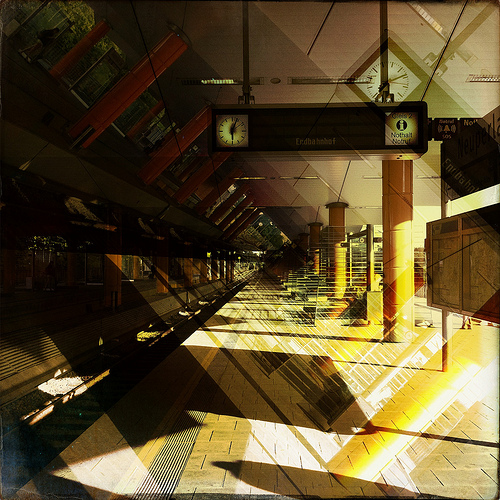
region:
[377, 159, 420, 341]
a cylindrical orange column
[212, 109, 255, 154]
a clock at a train station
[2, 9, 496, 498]
a train station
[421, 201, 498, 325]
a sign at a train station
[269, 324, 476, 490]
concrete tiles on the floor of a train station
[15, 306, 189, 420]
train tracks at a train station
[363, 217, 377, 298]
a support post at a train station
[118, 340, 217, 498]
a yellow stripe on a train platform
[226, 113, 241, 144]
black hands on a clock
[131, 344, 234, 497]
black rubber padding at a train station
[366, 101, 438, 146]
Sign with i and words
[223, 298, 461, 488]
very unique reflection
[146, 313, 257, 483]
Steel grates on ground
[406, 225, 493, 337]
Large wooden sign facing away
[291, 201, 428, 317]
Large supporting pillars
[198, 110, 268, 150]
Analog clock thats not illuminated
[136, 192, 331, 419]
Large long hallway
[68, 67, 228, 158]
Red pillars leaning inward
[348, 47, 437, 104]
Analog white clock on ceiling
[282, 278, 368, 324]
Stand/rack for putting items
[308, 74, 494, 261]
the pillar is yellow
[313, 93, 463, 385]
the pillar is yellow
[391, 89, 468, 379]
the pillar is yellow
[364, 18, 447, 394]
the pillar is yellow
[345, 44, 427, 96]
A clock is at the top of the ceiling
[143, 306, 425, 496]
Shadows are on the floor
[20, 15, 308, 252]
The roof has lots of windows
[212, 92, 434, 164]
A sign tells the name of the station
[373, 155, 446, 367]
A yellow pole holds up the ceiling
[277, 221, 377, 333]
The terminal is closed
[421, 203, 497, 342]
A map shows you where you are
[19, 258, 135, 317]
This area is for people to wait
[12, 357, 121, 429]
The tracks are metal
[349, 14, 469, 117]
The ceiling is reflective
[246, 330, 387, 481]
the shadow is arrow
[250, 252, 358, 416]
the shadow is arrow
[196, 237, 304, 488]
the shadow is arrow